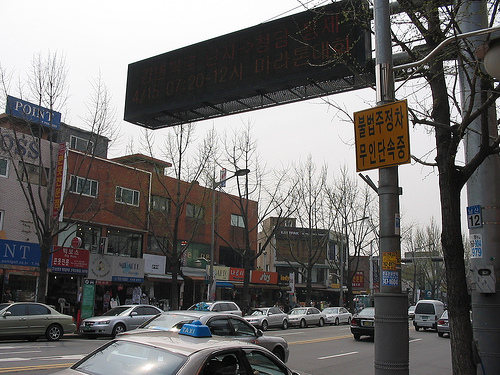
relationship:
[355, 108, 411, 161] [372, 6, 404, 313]
sign on pole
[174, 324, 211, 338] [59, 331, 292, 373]
taxi cab sign on car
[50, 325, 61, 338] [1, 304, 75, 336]
tire on car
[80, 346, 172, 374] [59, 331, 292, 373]
window on car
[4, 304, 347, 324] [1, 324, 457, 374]
cars parked on street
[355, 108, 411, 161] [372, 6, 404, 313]
sign on post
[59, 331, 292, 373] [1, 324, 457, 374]
taxi on street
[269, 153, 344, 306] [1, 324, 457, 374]
tree next to street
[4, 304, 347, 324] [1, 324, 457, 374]
cars on street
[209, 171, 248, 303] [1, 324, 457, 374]
light pole on street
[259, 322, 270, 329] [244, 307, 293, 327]
wheel on car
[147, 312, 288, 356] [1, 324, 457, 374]
car on street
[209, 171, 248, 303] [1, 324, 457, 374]
street lamp along street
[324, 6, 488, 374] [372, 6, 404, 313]
tree next to post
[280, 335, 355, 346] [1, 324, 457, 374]
yellow stripe on street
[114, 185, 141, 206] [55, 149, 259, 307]
window on building